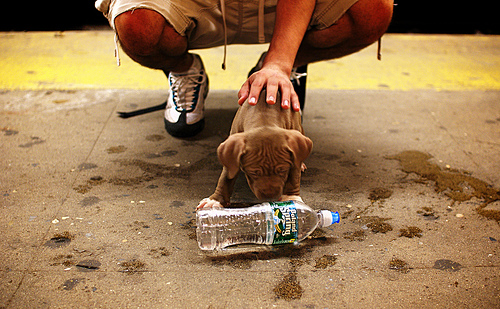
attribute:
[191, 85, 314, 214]
puppy — little, brown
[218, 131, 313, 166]
ears — floppy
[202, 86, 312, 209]
puppy — young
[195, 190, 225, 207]
paw — white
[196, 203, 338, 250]
bottle — water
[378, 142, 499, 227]
water — puddle, small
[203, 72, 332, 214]
puppy — brown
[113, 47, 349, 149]
shoes — black and white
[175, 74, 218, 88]
slaces — white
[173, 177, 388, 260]
bottle — plastic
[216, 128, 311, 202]
face — wrinkled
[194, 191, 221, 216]
paw — white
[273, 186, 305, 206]
paw — white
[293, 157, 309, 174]
paw — white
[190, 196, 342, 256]
bottle — plastic, water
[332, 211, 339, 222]
cap — blue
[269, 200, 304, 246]
label — green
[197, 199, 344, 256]
water bottle — tipped over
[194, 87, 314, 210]
dog — little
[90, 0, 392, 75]
shorts — brown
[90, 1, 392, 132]
man — young